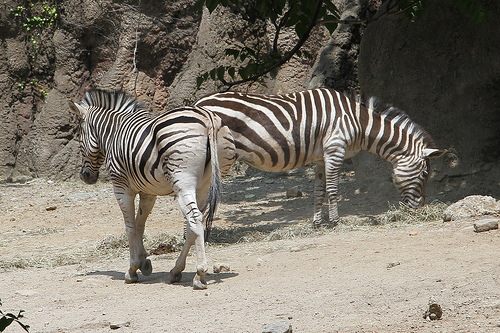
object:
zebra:
[66, 88, 226, 291]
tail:
[202, 122, 223, 242]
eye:
[421, 170, 429, 178]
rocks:
[12, 272, 85, 315]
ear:
[67, 99, 85, 118]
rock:
[259, 320, 292, 333]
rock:
[109, 321, 130, 329]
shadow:
[77, 269, 239, 287]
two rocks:
[440, 194, 499, 233]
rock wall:
[0, 0, 358, 181]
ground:
[0, 171, 500, 333]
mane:
[343, 88, 437, 148]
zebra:
[183, 87, 449, 240]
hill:
[0, 193, 500, 333]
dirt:
[0, 165, 500, 333]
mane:
[80, 87, 145, 113]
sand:
[0, 178, 500, 333]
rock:
[472, 215, 500, 232]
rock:
[440, 194, 500, 222]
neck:
[361, 95, 416, 164]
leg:
[113, 184, 142, 269]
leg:
[135, 192, 157, 253]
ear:
[422, 148, 448, 159]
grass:
[366, 200, 454, 230]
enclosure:
[0, 0, 500, 333]